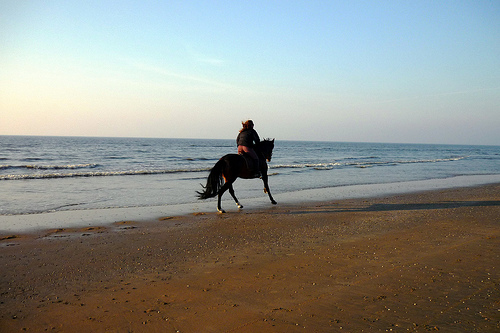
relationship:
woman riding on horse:
[229, 116, 264, 160] [202, 138, 282, 217]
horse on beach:
[202, 138, 282, 217] [12, 218, 493, 319]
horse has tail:
[202, 138, 282, 217] [197, 165, 226, 203]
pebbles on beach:
[97, 280, 141, 306] [12, 218, 493, 319]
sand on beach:
[15, 224, 256, 246] [12, 218, 493, 319]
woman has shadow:
[229, 116, 264, 160] [276, 195, 500, 222]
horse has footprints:
[202, 138, 282, 217] [113, 221, 139, 236]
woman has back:
[229, 116, 264, 160] [236, 131, 253, 143]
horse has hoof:
[202, 138, 282, 217] [234, 199, 244, 212]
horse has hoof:
[202, 138, 282, 217] [218, 207, 231, 218]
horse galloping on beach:
[202, 138, 282, 217] [12, 218, 493, 319]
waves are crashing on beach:
[4, 159, 186, 181] [12, 218, 493, 319]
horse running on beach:
[202, 138, 282, 217] [12, 218, 493, 319]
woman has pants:
[229, 116, 264, 160] [237, 144, 260, 160]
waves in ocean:
[4, 159, 186, 181] [9, 128, 496, 189]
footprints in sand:
[113, 221, 139, 236] [15, 224, 256, 246]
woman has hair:
[229, 116, 264, 160] [238, 119, 254, 132]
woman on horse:
[229, 116, 264, 160] [202, 138, 282, 217]